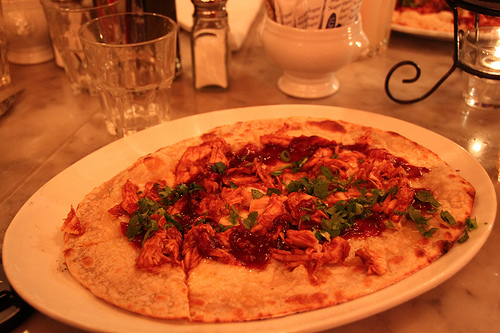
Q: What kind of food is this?
A: Flatbread.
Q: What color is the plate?
A: White.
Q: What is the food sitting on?
A: Plate.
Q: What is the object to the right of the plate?
A: Candle.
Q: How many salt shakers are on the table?
A: One.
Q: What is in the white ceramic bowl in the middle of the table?
A: Sugar.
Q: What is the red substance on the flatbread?
A: Red sauce.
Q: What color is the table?
A: Tan.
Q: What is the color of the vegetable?
A: Green.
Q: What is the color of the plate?
A: White.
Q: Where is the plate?
A: On the table.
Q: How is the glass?
A: Empty.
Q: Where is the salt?
A: Beside the glass.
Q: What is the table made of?
A: Marble.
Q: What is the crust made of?
A: Flour.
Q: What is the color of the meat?
A: Brown.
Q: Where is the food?
A: On the plate.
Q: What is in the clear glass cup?
A: Nothing.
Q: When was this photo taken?
A: During a mealtime.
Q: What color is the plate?
A: White.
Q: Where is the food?
A: On the table.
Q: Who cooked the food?
A: The chef.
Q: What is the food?
A: Pizza.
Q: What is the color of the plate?
A: White.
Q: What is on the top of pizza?
A: Parsley.